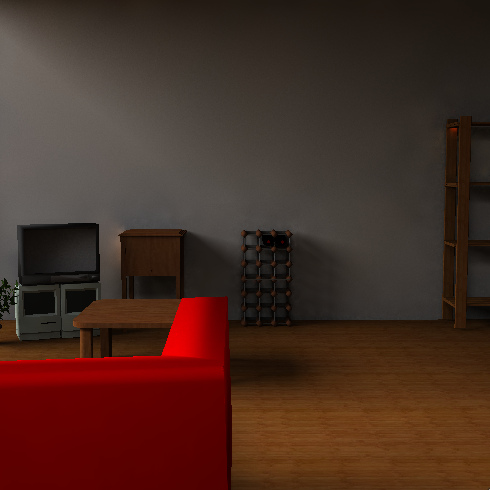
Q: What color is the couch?
A: Red.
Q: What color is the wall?
A: Gray.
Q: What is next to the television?
A: A table.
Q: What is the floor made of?
A: Wood.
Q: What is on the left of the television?
A: A plant.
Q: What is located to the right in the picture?
A: Shelves.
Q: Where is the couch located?
A: On the left.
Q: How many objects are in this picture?
A: Nine.